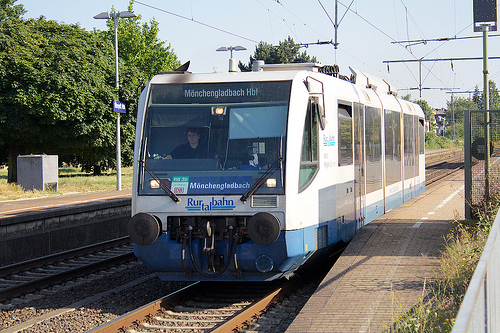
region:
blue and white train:
[133, 76, 427, 285]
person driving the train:
[162, 127, 206, 157]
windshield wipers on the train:
[139, 147, 282, 204]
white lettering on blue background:
[191, 175, 249, 191]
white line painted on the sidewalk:
[358, 155, 499, 330]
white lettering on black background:
[177, 79, 263, 100]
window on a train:
[145, 95, 290, 185]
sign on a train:
[165, 80, 275, 105]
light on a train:
[265, 171, 280, 191]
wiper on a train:
[255, 150, 285, 170]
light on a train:
[142, 176, 157, 192]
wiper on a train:
[135, 152, 151, 177]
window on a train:
[335, 106, 353, 176]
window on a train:
[366, 96, 381, 196]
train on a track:
[135, 72, 306, 278]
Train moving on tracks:
[130, 54, 429, 280]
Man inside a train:
[162, 126, 204, 158]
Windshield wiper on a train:
[241, 134, 285, 199]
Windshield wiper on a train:
[136, 136, 177, 201]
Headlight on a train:
[145, 178, 166, 187]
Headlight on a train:
[260, 175, 277, 187]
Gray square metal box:
[17, 153, 64, 192]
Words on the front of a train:
[182, 193, 234, 212]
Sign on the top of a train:
[180, 83, 263, 95]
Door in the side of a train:
[351, 99, 367, 227]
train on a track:
[125, 8, 440, 332]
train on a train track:
[153, 10, 403, 331]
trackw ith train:
[94, 45, 474, 325]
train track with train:
[165, 73, 327, 332]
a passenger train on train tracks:
[92, 16, 495, 318]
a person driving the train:
[169, 106, 211, 163]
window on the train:
[148, 84, 286, 188]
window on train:
[341, 105, 363, 150]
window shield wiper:
[227, 144, 311, 232]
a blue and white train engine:
[126, 63, 360, 281]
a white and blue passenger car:
[381, 90, 428, 204]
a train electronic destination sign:
[179, 83, 259, 103]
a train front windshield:
[141, 103, 283, 173]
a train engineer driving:
[160, 126, 204, 157]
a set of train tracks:
[85, 278, 290, 330]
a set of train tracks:
[0, 235, 132, 302]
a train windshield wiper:
[140, 136, 178, 203]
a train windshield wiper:
[237, 133, 286, 200]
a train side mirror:
[302, 72, 329, 129]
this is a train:
[63, 14, 469, 330]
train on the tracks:
[74, 6, 451, 328]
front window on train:
[133, 87, 294, 219]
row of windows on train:
[326, 82, 428, 219]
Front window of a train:
[130, 71, 300, 171]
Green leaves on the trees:
[0, 0, 190, 175]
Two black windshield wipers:
[125, 141, 285, 206]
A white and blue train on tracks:
[80, 52, 455, 327]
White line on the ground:
[348, 147, 493, 328]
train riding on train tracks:
[127, 56, 427, 283]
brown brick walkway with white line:
[283, 154, 498, 331]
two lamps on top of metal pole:
[92, 10, 135, 193]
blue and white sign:
[110, 99, 127, 113]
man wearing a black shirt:
[149, 125, 219, 160]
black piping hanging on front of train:
[179, 215, 240, 282]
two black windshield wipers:
[136, 153, 283, 202]